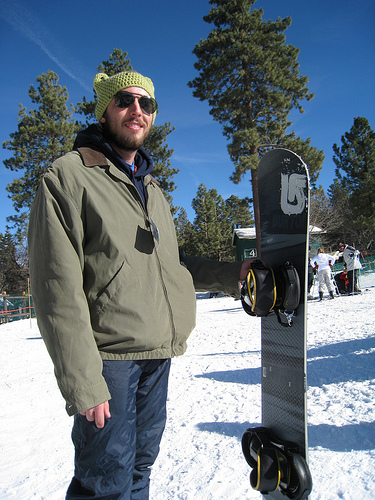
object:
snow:
[0, 264, 375, 499]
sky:
[0, 0, 375, 268]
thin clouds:
[2, 2, 94, 100]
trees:
[188, 0, 326, 259]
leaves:
[35, 109, 57, 147]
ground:
[0, 274, 375, 500]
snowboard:
[239, 147, 312, 499]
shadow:
[196, 416, 374, 451]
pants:
[67, 359, 172, 499]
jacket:
[28, 145, 242, 416]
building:
[230, 224, 328, 264]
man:
[29, 72, 257, 498]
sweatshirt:
[72, 122, 154, 211]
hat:
[93, 71, 157, 126]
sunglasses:
[113, 89, 158, 114]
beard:
[102, 107, 152, 151]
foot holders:
[240, 259, 276, 318]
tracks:
[0, 272, 375, 499]